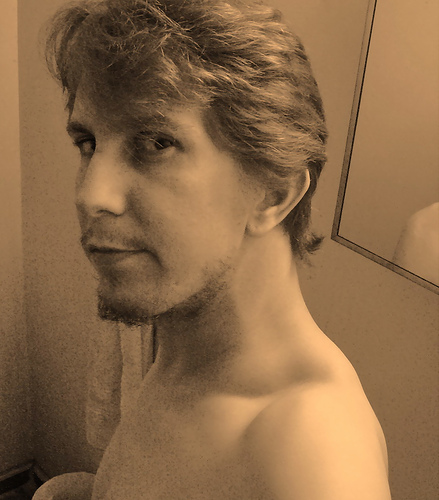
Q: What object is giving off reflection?
A: Mirror.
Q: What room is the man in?
A: Bathroom.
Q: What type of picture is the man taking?
A: Selfie.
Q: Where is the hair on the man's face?
A: Chin.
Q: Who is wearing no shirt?
A: A man.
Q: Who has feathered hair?
A: The man.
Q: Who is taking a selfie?
A: The man.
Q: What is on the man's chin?
A: A scraggly beard.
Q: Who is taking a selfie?
A: A man with no shirt.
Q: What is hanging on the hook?
A: A towel.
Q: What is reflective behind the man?
A: The medicine cabinet.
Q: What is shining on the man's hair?
A: Light.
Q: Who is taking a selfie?
A: The man.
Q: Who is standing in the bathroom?
A: A shirtless man.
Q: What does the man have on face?
A: Facial hair.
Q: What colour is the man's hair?
A: Blonde.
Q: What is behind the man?
A: Shower curtain.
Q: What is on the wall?
A: Mirror.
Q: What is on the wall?
A: A framed mirror.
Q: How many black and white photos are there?
A: 1.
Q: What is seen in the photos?
A: Men with facial hair.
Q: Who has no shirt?
A: The man.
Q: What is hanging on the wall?
A: Mirror.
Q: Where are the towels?
A: On the wall.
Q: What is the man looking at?
A: The camera.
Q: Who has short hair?
A: The man.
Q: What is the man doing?
A: Taking a selfie.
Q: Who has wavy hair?
A: The man.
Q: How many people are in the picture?
A: 1.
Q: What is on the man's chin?
A: A beard.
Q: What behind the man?
A: A mirror.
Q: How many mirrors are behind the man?
A: 1.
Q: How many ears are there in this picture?
A: 1.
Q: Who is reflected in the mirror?
A: The man.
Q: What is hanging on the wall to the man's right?
A: A towel.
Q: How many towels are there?
A: 1.